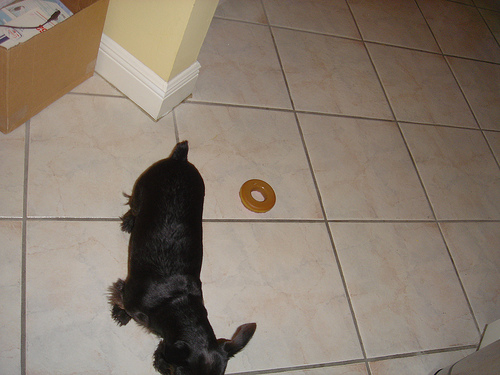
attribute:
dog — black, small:
[116, 145, 242, 353]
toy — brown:
[229, 174, 287, 219]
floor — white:
[224, 21, 494, 305]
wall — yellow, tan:
[121, 3, 207, 119]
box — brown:
[0, 0, 106, 131]